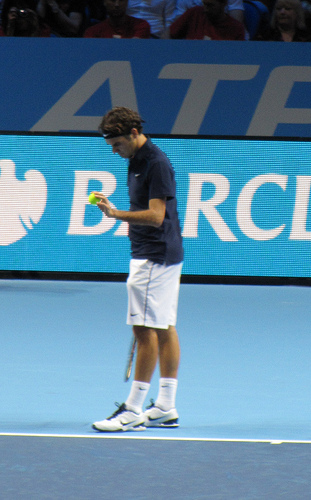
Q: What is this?
A: Tennis pitch.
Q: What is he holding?
A: A racket.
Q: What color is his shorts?
A: White.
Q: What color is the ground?
A: Blue.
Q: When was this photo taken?
A: During a tennis game.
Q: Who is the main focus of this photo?
A: A tennis player.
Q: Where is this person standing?
A: On a tennis court.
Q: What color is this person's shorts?
A: White.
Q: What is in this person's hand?
A: A tennis ball.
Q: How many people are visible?
A: One.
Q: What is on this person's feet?
A: Sneakers.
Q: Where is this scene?
A: At a tennis court.